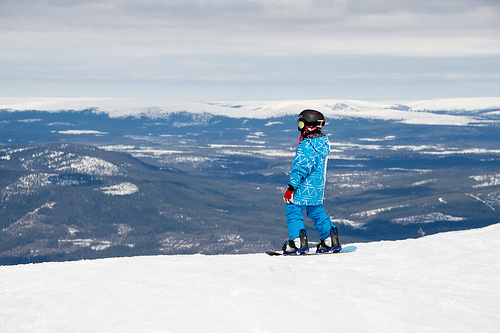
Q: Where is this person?
A: On a mountain.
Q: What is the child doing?
A: Snowboarding.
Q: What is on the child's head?
A: A helmet.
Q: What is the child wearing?
A: A coat and snowpants.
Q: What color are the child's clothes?
A: Turquoise.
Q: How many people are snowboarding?
A: One.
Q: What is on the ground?
A: Snow.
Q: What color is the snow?
A: White.